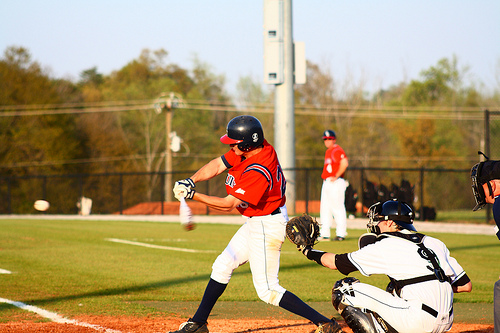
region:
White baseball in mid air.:
[30, 192, 65, 216]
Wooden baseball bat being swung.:
[174, 185, 198, 240]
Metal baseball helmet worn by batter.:
[214, 110, 264, 148]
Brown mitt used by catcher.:
[283, 198, 321, 251]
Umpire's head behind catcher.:
[471, 156, 498, 214]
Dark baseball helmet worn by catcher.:
[376, 196, 425, 238]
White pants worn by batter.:
[207, 203, 296, 301]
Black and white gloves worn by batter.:
[172, 169, 197, 200]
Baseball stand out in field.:
[311, 123, 351, 242]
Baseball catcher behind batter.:
[287, 183, 469, 332]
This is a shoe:
[170, 314, 210, 331]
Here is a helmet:
[219, 112, 267, 153]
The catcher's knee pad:
[328, 275, 358, 309]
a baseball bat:
[171, 186, 198, 232]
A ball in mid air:
[30, 196, 52, 215]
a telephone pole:
[152, 87, 177, 208]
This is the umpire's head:
[466, 155, 499, 212]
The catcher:
[286, 199, 475, 332]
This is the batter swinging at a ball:
[174, 114, 344, 331]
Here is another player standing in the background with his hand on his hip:
[317, 126, 350, 242]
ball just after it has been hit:
[20, 182, 60, 223]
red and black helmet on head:
[216, 116, 265, 158]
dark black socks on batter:
[197, 274, 228, 331]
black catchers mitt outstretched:
[291, 206, 330, 259]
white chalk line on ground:
[123, 228, 177, 263]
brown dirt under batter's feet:
[71, 305, 141, 331]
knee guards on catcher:
[326, 274, 367, 309]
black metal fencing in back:
[106, 176, 165, 216]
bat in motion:
[165, 189, 211, 234]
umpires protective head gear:
[456, 152, 497, 214]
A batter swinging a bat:
[162, 117, 334, 327]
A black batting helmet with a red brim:
[218, 114, 268, 154]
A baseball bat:
[168, 189, 198, 232]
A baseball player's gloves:
[170, 173, 195, 203]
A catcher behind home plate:
[283, 192, 468, 331]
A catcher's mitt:
[286, 209, 320, 252]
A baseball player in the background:
[315, 121, 350, 244]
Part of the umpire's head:
[460, 156, 497, 213]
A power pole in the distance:
[140, 92, 197, 210]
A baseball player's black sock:
[183, 269, 227, 326]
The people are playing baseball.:
[0, 91, 498, 331]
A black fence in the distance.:
[0, 105, 495, 212]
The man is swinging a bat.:
[165, 175, 205, 242]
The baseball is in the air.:
[30, 192, 55, 212]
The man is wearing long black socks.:
[170, 277, 327, 327]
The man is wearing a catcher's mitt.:
[280, 211, 320, 251]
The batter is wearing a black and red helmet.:
[216, 115, 266, 160]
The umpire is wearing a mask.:
[460, 150, 496, 210]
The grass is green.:
[40, 245, 130, 280]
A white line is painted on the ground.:
[5, 295, 96, 330]